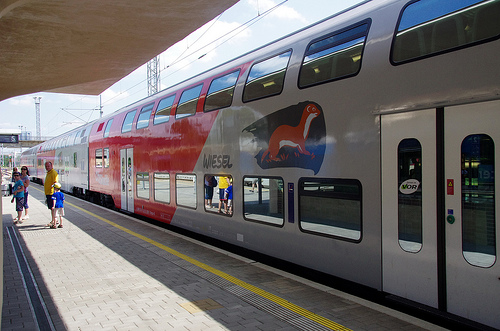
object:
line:
[28, 178, 350, 330]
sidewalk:
[0, 179, 443, 330]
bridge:
[0, 139, 45, 148]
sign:
[0, 133, 19, 144]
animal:
[260, 103, 320, 164]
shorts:
[46, 195, 54, 209]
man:
[43, 160, 60, 229]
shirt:
[50, 191, 65, 209]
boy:
[50, 181, 66, 228]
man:
[10, 172, 25, 225]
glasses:
[12, 174, 22, 177]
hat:
[51, 181, 63, 188]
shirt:
[44, 170, 60, 195]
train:
[16, 0, 500, 331]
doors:
[378, 108, 441, 308]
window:
[388, 0, 499, 67]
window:
[296, 17, 373, 90]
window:
[241, 48, 293, 103]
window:
[202, 67, 241, 113]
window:
[173, 82, 203, 120]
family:
[11, 161, 64, 229]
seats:
[300, 220, 361, 241]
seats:
[242, 212, 284, 226]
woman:
[12, 165, 31, 220]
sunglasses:
[21, 167, 27, 170]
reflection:
[204, 174, 232, 217]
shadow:
[69, 204, 447, 331]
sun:
[10, 185, 228, 330]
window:
[202, 173, 235, 218]